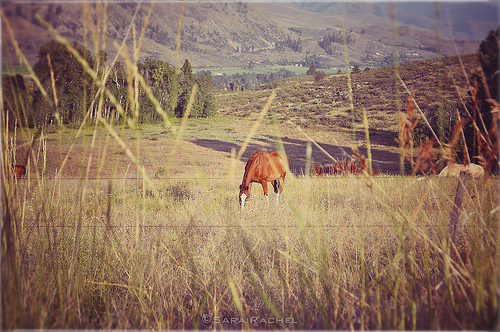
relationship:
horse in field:
[214, 146, 292, 211] [41, 115, 495, 301]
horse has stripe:
[214, 146, 292, 211] [239, 191, 249, 209]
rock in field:
[441, 158, 484, 180] [41, 115, 495, 301]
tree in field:
[394, 71, 419, 172] [41, 115, 495, 301]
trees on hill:
[298, 56, 375, 78] [280, 45, 478, 130]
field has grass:
[41, 115, 495, 301] [169, 194, 374, 240]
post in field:
[452, 163, 472, 263] [41, 115, 495, 301]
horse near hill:
[214, 146, 292, 211] [280, 45, 478, 130]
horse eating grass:
[214, 146, 292, 211] [169, 194, 374, 240]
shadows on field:
[202, 124, 416, 175] [41, 115, 495, 301]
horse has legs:
[214, 146, 292, 211] [257, 180, 294, 205]